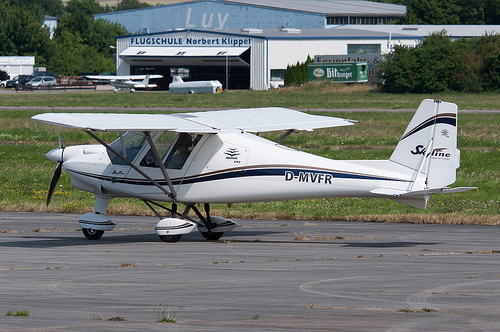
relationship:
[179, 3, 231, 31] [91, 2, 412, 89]
word "luv" on building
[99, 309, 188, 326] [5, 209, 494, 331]
grass sticking out of pavement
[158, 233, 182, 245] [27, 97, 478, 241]
wheel of aircraft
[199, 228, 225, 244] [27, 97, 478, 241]
wheel of aircraft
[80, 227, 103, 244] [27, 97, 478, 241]
wheel of aircraft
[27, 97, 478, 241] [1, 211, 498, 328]
aircraft of runway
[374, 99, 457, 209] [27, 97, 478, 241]
tail of aircraft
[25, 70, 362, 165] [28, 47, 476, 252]
wings of plane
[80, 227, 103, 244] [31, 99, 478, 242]
wheel of aircraft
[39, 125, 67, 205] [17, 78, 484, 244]
propeller in front of plane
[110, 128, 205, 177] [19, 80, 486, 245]
cockpit of aircraft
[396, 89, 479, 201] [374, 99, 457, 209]
fins on tail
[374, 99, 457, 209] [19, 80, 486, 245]
tail of aircraft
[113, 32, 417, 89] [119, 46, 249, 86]
building has door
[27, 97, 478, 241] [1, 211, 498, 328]
aircraft on runway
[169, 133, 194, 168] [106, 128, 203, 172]
guy on cockpit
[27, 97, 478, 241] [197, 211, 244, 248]
aircraft has wheel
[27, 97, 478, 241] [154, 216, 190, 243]
aircraft has wheel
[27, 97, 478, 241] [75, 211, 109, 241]
aircraft has wheel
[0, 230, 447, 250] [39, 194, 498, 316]
shadow on ground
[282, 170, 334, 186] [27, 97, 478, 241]
writing on aircraft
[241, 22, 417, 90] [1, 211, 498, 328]
building on other side of runway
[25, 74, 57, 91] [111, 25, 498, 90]
car parked by building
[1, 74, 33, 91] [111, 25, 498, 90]
car parked by building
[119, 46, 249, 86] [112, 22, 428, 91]
door on airplane hanger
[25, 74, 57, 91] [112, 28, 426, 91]
car parked next to airplane hanger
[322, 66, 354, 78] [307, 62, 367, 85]
lettering on green trailer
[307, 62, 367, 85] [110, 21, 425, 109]
green trailer next to hanger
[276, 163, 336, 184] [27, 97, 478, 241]
identification on side of aircraft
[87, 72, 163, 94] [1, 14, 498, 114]
plane in background